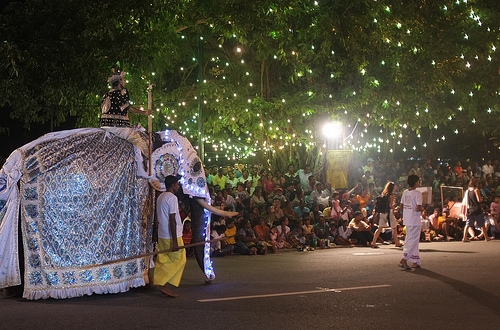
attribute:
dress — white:
[401, 188, 421, 260]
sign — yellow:
[321, 148, 353, 189]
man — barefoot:
[149, 173, 189, 300]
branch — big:
[265, 0, 325, 100]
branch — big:
[140, 0, 207, 76]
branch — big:
[423, 1, 499, 88]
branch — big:
[222, 1, 266, 123]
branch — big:
[311, 0, 385, 68]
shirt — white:
[155, 193, 188, 240]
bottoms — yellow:
[146, 234, 195, 287]